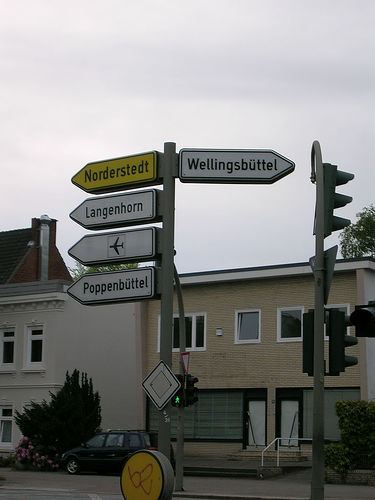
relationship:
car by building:
[59, 427, 175, 476] [21, 209, 273, 460]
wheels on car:
[61, 459, 75, 473] [33, 414, 223, 484]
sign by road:
[79, 192, 157, 234] [10, 455, 221, 493]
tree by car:
[22, 357, 102, 467] [61, 419, 174, 467]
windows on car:
[80, 429, 146, 450] [59, 427, 175, 476]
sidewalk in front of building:
[185, 451, 302, 470] [142, 250, 374, 455]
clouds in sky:
[0, 0, 375, 247] [2, 1, 374, 280]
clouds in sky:
[96, 104, 276, 134] [2, 1, 374, 280]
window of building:
[321, 305, 349, 339] [182, 264, 370, 456]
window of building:
[173, 313, 197, 351] [147, 261, 373, 477]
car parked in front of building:
[59, 427, 175, 476] [2, 256, 372, 463]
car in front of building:
[56, 427, 176, 476] [2, 256, 372, 463]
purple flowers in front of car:
[7, 429, 68, 476] [61, 423, 173, 478]